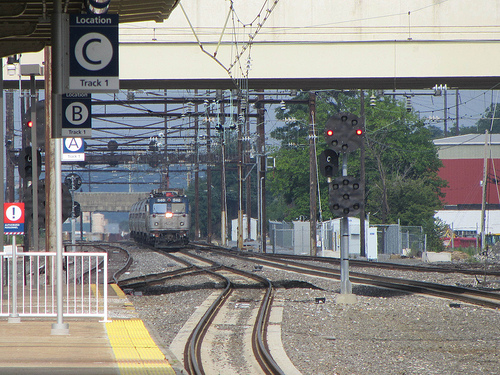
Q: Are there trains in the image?
A: Yes, there is a train.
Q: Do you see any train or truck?
A: Yes, there is a train.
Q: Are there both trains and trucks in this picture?
A: No, there is a train but no trucks.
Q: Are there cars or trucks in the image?
A: No, there are no cars or trucks.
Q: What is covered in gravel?
A: The ground is covered in gravel.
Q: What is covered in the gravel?
A: The ground is covered in gravel.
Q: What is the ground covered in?
A: The ground is covered in gravel.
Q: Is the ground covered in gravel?
A: Yes, the ground is covered in gravel.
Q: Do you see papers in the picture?
A: No, there are no papers.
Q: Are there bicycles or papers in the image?
A: No, there are no papers or bicycles.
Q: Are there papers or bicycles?
A: No, there are no papers or bicycles.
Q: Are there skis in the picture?
A: No, there are no skis.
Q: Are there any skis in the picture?
A: No, there are no skis.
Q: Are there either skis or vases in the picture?
A: No, there are no skis or vases.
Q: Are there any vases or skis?
A: No, there are no skis or vases.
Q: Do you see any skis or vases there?
A: No, there are no skis or vases.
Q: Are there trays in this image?
A: No, there are no trays.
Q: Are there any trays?
A: No, there are no trays.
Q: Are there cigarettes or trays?
A: No, there are no trays or cigarettes.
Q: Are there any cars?
A: No, there are no cars.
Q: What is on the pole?
A: The sign is on the pole.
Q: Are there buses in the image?
A: No, there are no buses.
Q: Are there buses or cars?
A: No, there are no buses or cars.